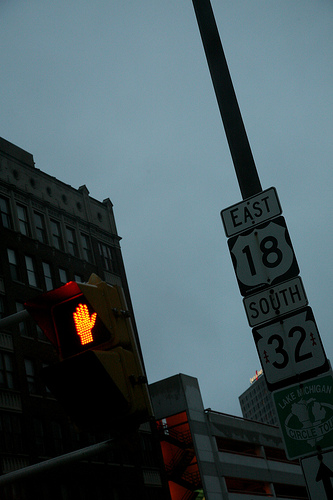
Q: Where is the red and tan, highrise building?
A: Across from the pole with signs on it.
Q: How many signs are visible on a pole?
A: Five.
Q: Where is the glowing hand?
A: On a traffic light.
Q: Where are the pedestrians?
A: None are visible.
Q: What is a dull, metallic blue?
A: The sky.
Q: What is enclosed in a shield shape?
A: The number 18.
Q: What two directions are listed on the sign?
A: East and south.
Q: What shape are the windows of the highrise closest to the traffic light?
A: Rectangular.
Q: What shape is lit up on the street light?
A: A hand.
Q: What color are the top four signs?
A: Black and white.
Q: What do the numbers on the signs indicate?
A: Highways.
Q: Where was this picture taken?
A: City.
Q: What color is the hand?
A: Yellow.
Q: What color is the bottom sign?
A: Green and white.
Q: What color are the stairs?
A: Black.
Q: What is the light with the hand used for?
A: To indicate cross walk safety.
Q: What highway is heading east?
A: 18.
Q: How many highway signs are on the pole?
A: 2.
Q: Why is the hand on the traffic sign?
A: To advise pedestrians when to walk.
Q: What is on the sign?
A: Numbers.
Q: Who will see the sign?
A: People.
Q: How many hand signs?
A: 1.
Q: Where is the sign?
A: In front of the building.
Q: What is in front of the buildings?
A: Signs.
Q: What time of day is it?
A: Evening.